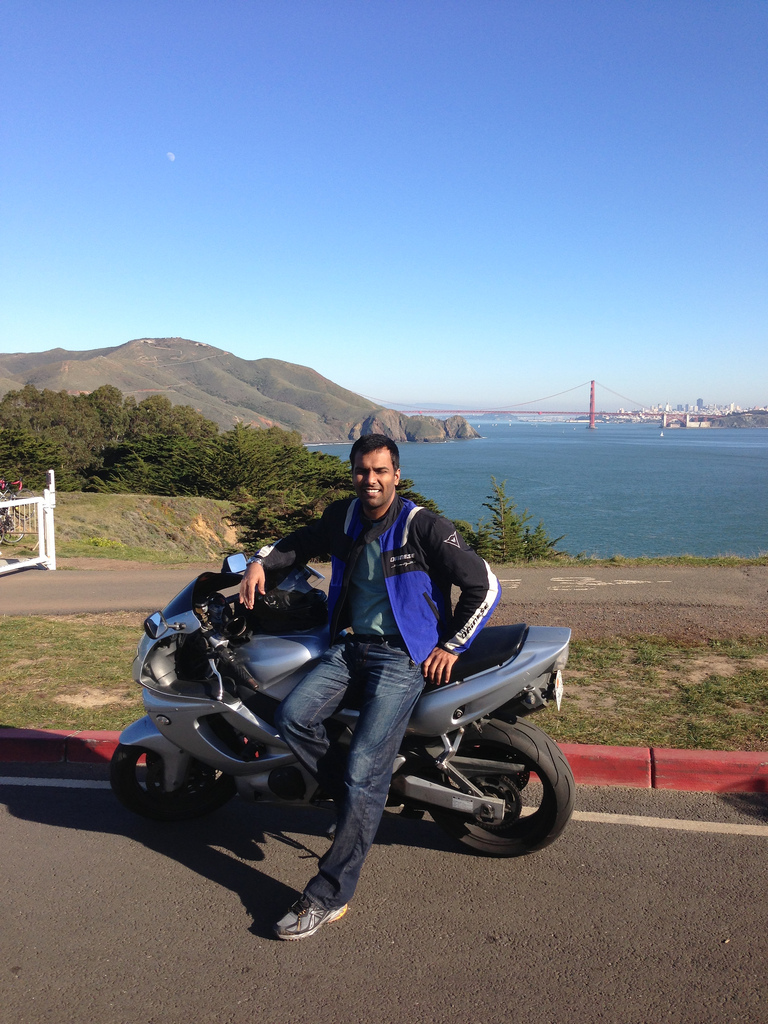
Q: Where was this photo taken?
A: The street.